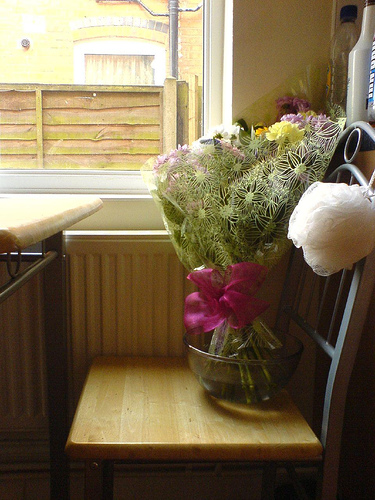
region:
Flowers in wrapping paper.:
[169, 104, 303, 343]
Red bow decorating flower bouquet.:
[141, 118, 277, 333]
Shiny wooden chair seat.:
[79, 345, 316, 453]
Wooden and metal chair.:
[72, 164, 369, 454]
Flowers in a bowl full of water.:
[185, 163, 318, 405]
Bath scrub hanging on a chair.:
[289, 180, 374, 276]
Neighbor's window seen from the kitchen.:
[1, 0, 191, 75]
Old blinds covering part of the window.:
[1, 81, 168, 173]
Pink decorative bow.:
[180, 260, 267, 325]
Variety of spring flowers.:
[155, 111, 336, 401]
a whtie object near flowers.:
[272, 173, 373, 282]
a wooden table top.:
[57, 346, 322, 456]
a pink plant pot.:
[183, 253, 325, 401]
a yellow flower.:
[245, 111, 315, 170]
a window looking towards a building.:
[0, 4, 204, 87]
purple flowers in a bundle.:
[275, 91, 343, 129]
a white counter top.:
[66, 179, 171, 236]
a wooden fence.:
[0, 79, 207, 172]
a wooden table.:
[0, 193, 108, 237]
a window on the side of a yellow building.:
[66, 38, 180, 79]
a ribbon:
[183, 264, 281, 340]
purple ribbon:
[183, 270, 252, 334]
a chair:
[316, 350, 363, 395]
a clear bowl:
[204, 355, 242, 371]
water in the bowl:
[218, 381, 251, 402]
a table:
[6, 195, 52, 227]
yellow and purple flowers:
[241, 111, 318, 144]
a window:
[45, 120, 152, 171]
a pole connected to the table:
[27, 324, 80, 392]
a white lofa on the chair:
[304, 187, 373, 248]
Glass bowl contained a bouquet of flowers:
[138, 70, 347, 411]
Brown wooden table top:
[3, 190, 116, 256]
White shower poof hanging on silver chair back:
[289, 115, 373, 488]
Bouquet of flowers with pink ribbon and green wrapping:
[145, 81, 349, 400]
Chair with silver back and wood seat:
[62, 121, 372, 487]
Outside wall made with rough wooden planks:
[3, 71, 199, 171]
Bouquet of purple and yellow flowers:
[139, 78, 342, 413]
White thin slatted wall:
[7, 227, 345, 452]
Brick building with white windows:
[11, 7, 200, 82]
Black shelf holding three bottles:
[307, 5, 373, 150]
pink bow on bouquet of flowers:
[176, 256, 285, 341]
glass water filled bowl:
[182, 319, 308, 408]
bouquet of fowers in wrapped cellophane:
[145, 62, 353, 413]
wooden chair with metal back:
[64, 77, 372, 497]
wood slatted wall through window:
[1, 76, 191, 175]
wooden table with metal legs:
[0, 184, 78, 497]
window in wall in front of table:
[0, 1, 218, 193]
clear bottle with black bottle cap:
[324, 2, 365, 117]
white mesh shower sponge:
[286, 157, 373, 274]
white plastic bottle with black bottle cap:
[343, 0, 374, 130]